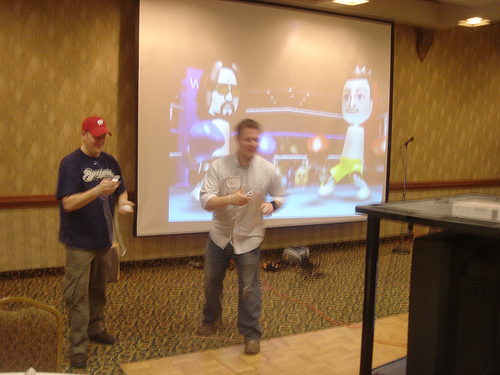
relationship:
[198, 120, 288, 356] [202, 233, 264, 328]
man in jeans.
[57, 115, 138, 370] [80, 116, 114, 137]
man in hat.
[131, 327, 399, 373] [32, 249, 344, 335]
mat on floor.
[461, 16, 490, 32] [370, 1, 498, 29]
light on ceiling.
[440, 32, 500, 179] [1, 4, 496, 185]
wallpaper on wall.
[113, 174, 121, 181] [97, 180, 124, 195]
remote in hand.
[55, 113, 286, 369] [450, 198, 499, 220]
guys playing wii.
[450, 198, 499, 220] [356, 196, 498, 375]
game on stand.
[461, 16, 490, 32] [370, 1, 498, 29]
light in ceiling.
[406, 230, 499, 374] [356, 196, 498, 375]
television on stand.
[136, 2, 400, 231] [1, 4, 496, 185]
screen on wall.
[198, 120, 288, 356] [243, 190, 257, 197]
man holding remote.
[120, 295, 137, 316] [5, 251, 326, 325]
pattern on carpet.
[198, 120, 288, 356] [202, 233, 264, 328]
person in jeans.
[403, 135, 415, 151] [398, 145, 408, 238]
microphone on stand.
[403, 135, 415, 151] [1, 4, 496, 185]
microphone next to wall.